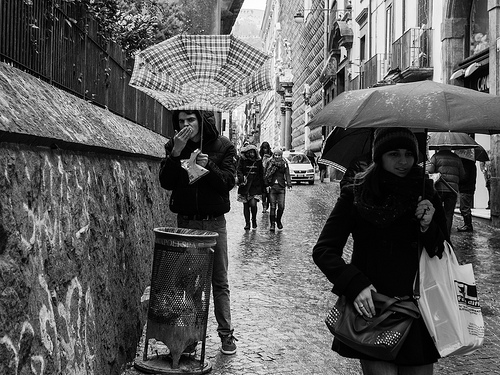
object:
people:
[458, 158, 478, 232]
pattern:
[374, 330, 402, 347]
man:
[159, 111, 239, 356]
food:
[180, 149, 210, 185]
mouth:
[184, 127, 192, 134]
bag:
[413, 240, 485, 359]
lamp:
[294, 13, 304, 24]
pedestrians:
[236, 144, 267, 229]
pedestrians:
[259, 141, 275, 213]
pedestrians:
[263, 147, 292, 231]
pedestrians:
[426, 146, 468, 247]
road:
[254, 273, 293, 367]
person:
[313, 126, 450, 358]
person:
[307, 156, 316, 168]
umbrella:
[451, 143, 491, 163]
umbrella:
[427, 132, 480, 150]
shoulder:
[339, 176, 378, 207]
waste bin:
[134, 227, 220, 375]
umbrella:
[314, 127, 429, 174]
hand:
[415, 196, 436, 227]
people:
[318, 164, 327, 184]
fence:
[20, 27, 119, 95]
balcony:
[392, 28, 435, 82]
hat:
[374, 127, 419, 164]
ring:
[359, 304, 364, 308]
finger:
[353, 301, 363, 315]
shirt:
[313, 165, 449, 304]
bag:
[325, 292, 422, 362]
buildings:
[258, 0, 497, 228]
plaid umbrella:
[129, 34, 275, 114]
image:
[454, 279, 482, 314]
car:
[282, 151, 315, 185]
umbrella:
[304, 80, 500, 132]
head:
[373, 128, 420, 178]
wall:
[320, 2, 448, 92]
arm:
[423, 178, 448, 259]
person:
[340, 152, 373, 189]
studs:
[325, 307, 340, 326]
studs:
[374, 331, 402, 347]